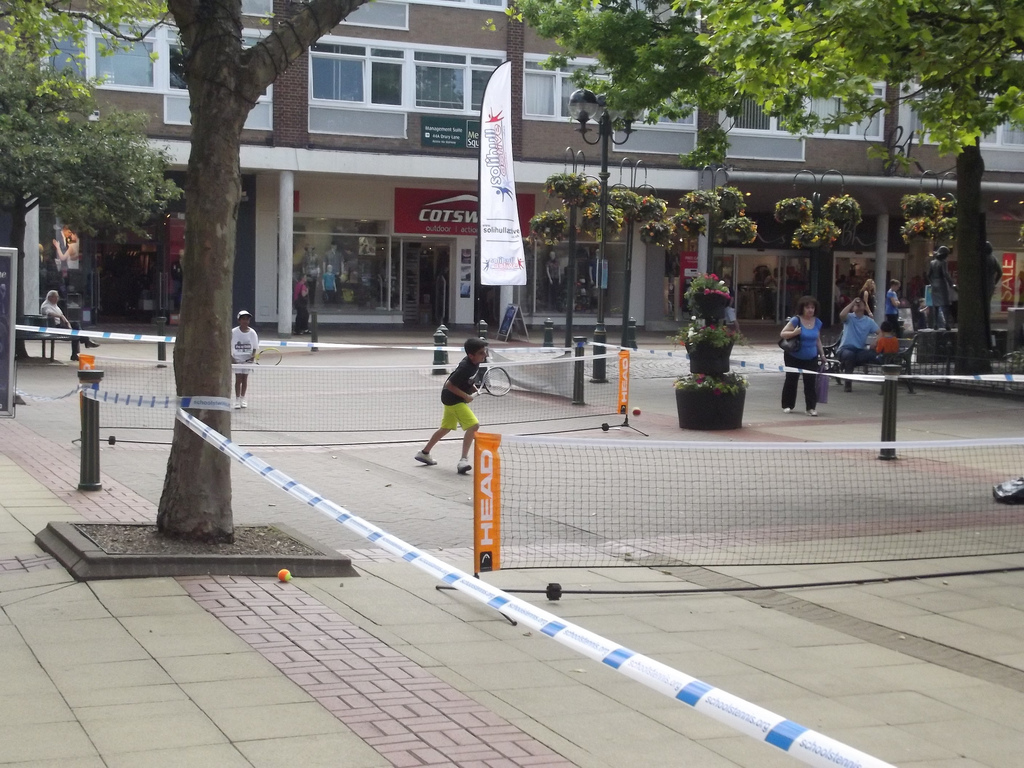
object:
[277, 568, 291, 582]
ball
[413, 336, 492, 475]
boy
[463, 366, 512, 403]
racket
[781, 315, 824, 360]
shirt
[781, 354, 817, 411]
pants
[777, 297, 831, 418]
woman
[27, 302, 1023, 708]
tennis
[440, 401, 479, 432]
shorts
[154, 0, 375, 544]
tree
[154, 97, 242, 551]
trunk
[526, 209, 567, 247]
flowers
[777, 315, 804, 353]
purse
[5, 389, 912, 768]
tape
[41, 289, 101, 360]
man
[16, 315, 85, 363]
bench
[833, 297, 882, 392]
man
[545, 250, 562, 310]
people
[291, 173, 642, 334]
store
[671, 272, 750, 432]
plants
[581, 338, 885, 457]
middle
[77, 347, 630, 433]
net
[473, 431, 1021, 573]
net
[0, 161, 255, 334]
shop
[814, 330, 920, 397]
bench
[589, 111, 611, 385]
post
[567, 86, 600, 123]
lamp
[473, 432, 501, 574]
end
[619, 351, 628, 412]
end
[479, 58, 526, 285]
banner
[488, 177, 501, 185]
words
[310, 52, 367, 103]
window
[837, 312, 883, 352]
shirt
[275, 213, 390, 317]
window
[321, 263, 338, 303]
mannequin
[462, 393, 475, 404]
hand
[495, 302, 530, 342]
board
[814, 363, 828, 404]
bag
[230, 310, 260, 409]
someone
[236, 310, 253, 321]
cap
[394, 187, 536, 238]
sign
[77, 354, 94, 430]
border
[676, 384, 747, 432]
pot